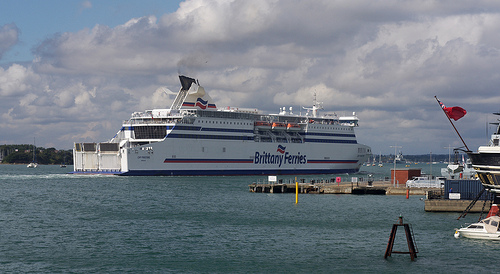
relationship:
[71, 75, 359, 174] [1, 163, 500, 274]
ship floating in water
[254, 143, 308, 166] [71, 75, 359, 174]
logo on side of ship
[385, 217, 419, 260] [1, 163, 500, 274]
buoy in water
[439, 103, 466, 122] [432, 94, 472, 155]
flag on pole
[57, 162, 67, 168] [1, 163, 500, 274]
boat floating in water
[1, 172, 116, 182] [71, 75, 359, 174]
water behind ship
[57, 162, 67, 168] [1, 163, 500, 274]
boat in water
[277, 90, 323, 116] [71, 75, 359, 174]
antennas are on ship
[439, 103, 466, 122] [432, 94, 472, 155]
flag attached to pole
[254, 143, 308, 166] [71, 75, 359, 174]
logo on ship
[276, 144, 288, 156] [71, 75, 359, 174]
flag image on ship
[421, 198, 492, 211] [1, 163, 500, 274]
concrete in water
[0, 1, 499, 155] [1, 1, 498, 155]
clouds are in sky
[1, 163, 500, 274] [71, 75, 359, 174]
water surrounds ship